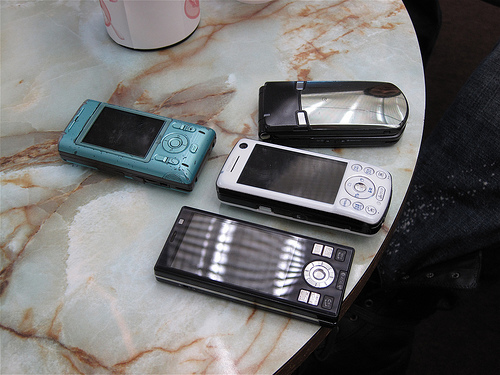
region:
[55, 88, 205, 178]
cell phone laying on table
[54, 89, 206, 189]
blue camera laying on table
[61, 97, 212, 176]
old cell phone on table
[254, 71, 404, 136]
black cell phone on table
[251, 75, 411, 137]
black flip phone on table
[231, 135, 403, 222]
white cell phone on table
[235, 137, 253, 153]
small camera on front of phone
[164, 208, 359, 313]
new black cell phone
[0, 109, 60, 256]
white table with brown designs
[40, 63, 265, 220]
a blue cell phone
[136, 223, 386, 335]
a black cell phone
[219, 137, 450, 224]
a white cell phone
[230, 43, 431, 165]
a flip phone on a table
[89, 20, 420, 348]
four cell phones on a table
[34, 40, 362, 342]
a marble table with phones on it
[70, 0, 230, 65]
a cup on a table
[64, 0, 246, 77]
a white cup on a table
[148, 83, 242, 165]
buttons on a cell phone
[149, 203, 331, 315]
a screen on a cell phone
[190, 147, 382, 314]
these are the cameras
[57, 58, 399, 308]
the cameras are four in number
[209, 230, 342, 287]
the camera is off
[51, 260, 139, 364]
this is the table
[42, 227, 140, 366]
the table is white in color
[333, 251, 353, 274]
the camera is black in color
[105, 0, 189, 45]
this is a cup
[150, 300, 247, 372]
the table is round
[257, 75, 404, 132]
the far is closed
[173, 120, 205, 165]
the camera is blue in color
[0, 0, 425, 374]
a round marble table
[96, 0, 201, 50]
a paper cup on the table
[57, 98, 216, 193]
a green smartphone on the table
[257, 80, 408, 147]
a black flip phone on the table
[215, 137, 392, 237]
a white smartphone on the table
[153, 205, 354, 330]
a black smartphone on the table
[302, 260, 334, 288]
a round control on a smartphone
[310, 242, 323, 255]
a button on a smartphone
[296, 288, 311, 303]
a button on a smartphone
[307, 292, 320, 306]
a button on a smartphone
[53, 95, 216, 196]
a blue camera on the table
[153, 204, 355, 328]
a black camera on the table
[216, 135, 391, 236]
a white phone on the table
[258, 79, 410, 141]
a black and silver phone on the table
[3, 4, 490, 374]
phones sitting on a table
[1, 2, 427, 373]
a white and brown marble style table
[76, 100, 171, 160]
the screen of the camera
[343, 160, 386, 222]
the dials on the phone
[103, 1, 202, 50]
the bottom of a cup sitting on the table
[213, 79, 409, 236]
two cell phones sitting on a table